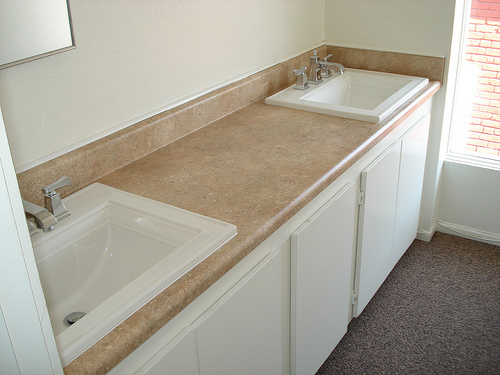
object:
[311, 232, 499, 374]
carpet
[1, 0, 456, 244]
wall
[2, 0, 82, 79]
mirror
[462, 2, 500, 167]
wall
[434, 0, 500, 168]
window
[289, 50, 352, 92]
faucet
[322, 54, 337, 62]
faucet handle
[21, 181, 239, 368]
bathroom sink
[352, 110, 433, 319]
cabinet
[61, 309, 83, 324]
drain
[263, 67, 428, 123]
sink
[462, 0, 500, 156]
brick wall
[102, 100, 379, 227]
counter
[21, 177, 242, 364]
sinks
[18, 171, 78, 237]
faucet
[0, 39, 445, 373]
backsplash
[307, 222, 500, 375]
floor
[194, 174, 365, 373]
cabinets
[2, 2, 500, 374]
bathroom